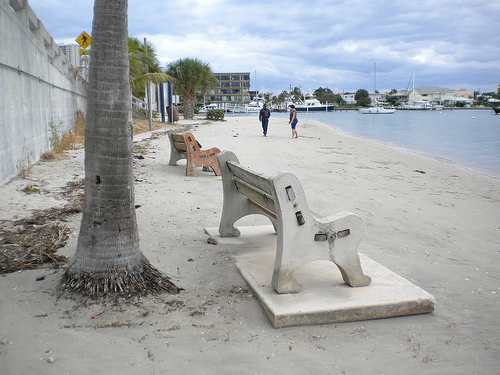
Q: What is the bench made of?
A: Concrete.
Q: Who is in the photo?
A: A couple.